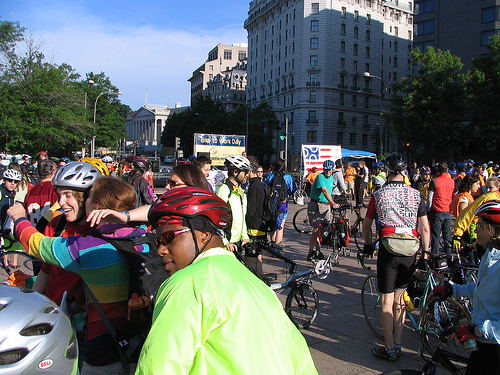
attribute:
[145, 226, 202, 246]
goggles — red, black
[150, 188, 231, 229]
helmet — shiny, black, red, silver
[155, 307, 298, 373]
jacket — shiny, green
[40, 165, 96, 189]
helmet — aerated, silver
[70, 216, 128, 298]
jacket — multicolored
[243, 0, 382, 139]
building — large, white, tall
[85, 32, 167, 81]
clouds — white, soft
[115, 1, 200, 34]
sky — blue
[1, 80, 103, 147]
trees — clustered, green, tall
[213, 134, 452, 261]
people — standing, crowd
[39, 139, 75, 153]
leaves — green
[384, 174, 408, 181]
skin — light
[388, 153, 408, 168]
helmet — black, white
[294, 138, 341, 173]
banner — red, white, blue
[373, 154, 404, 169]
helmet — black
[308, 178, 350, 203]
shirt — blue, teal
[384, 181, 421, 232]
shirt — red, black, white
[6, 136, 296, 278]
crowd — large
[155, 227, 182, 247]
sunglasses — red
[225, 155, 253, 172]
helmet — silver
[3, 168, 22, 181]
helmet — white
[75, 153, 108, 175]
helmet — yellow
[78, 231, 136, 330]
shirt — multicolored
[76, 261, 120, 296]
stripes — red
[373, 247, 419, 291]
shorts — black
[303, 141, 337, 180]
sign — white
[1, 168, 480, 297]
bicyclists — gathered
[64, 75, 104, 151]
tree — green